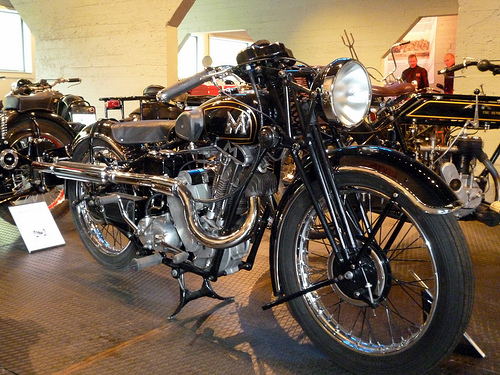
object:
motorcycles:
[1, 77, 96, 226]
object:
[7, 200, 68, 253]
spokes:
[382, 295, 395, 344]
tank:
[200, 97, 269, 145]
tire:
[67, 137, 138, 270]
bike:
[32, 39, 499, 374]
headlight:
[317, 57, 374, 132]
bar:
[155, 64, 235, 103]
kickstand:
[167, 267, 236, 319]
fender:
[269, 145, 464, 298]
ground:
[0, 216, 499, 374]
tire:
[277, 169, 477, 374]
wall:
[33, 24, 178, 122]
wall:
[448, 0, 499, 205]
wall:
[177, 0, 457, 87]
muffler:
[30, 159, 260, 248]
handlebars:
[155, 64, 237, 102]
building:
[0, 0, 499, 374]